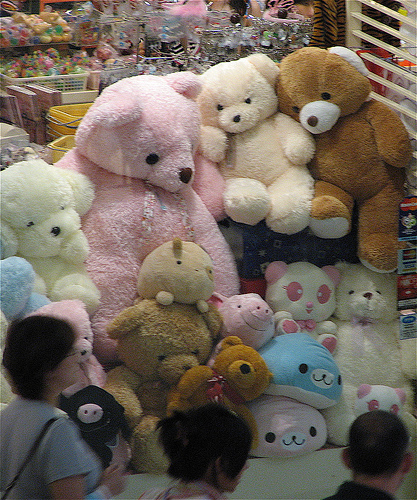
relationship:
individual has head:
[0, 315, 126, 500] [3, 314, 81, 398]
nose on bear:
[306, 115, 319, 128] [276, 46, 411, 276]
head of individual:
[337, 405, 413, 488] [320, 409, 414, 499]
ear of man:
[339, 446, 353, 469] [324, 411, 411, 498]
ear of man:
[405, 449, 415, 474] [324, 411, 411, 498]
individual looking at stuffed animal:
[321, 407, 413, 498] [264, 261, 341, 356]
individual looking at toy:
[321, 407, 413, 498] [246, 392, 327, 459]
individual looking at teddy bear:
[321, 407, 413, 498] [103, 298, 222, 475]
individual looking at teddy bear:
[321, 407, 413, 498] [325, 260, 416, 449]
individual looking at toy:
[321, 407, 413, 498] [0, 156, 103, 320]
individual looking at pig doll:
[0, 315, 126, 500] [59, 385, 133, 467]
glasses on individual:
[52, 347, 81, 367] [0, 315, 126, 500]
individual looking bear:
[0, 315, 126, 500] [57, 72, 274, 364]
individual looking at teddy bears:
[0, 315, 126, 500] [0, 47, 400, 288]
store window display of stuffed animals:
[5, 18, 406, 478] [0, 61, 409, 442]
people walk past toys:
[7, 307, 413, 480] [44, 55, 413, 482]